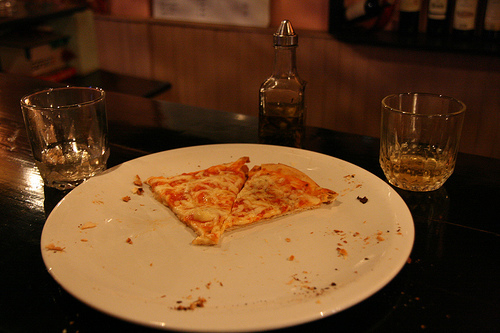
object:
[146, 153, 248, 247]
pizza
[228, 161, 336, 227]
slice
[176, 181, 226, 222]
cheese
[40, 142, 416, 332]
plate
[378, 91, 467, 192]
glass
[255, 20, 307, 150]
glass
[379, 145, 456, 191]
liquid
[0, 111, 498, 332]
table top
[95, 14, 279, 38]
slat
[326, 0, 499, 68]
rack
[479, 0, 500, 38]
wines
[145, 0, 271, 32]
board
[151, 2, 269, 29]
menu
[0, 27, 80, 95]
shelves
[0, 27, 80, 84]
items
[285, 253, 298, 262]
crumbs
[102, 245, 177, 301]
white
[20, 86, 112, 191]
glass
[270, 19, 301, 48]
spout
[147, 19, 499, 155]
paneling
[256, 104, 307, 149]
oil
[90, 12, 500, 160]
wall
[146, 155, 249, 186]
crust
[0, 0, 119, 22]
lights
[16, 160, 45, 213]
glare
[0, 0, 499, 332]
background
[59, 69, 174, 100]
bench